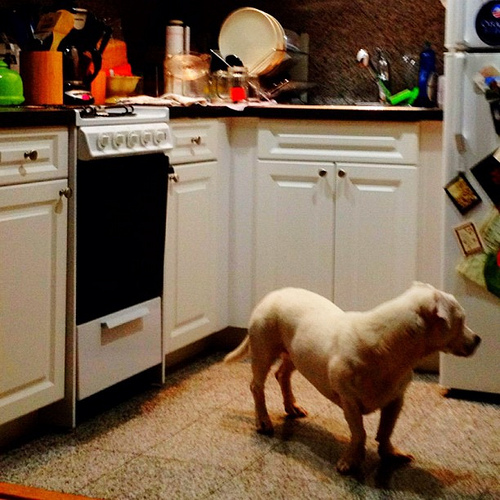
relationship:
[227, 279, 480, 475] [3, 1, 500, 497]
dog in kitchen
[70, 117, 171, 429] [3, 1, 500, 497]
oven in kitchen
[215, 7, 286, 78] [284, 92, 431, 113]
dishes next to sink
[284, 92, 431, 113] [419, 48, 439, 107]
sink with soap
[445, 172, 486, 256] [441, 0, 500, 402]
magnets on refrigerator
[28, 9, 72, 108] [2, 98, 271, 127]
utensils on counter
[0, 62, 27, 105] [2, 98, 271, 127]
teapot on counter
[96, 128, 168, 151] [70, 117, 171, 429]
buttons on oven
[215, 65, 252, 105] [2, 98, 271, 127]
mug on counter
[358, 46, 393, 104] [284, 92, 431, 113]
fixture for sink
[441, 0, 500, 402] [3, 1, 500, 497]
refrigerator in kitchen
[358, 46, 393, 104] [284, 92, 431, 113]
fixture over sink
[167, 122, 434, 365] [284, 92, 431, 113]
cabinets under sink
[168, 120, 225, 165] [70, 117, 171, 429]
drawer to right of oven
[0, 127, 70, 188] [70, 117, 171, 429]
drawer to left of oven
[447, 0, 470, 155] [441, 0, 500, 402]
handle on refrigerator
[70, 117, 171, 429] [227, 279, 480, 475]
oven next to dog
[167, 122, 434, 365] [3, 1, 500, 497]
cabinets in kitchen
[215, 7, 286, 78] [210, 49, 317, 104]
dishes on strainer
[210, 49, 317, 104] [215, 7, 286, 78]
strainer for dishes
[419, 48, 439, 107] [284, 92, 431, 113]
soap near sink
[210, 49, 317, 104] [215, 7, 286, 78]
strainer with dishes